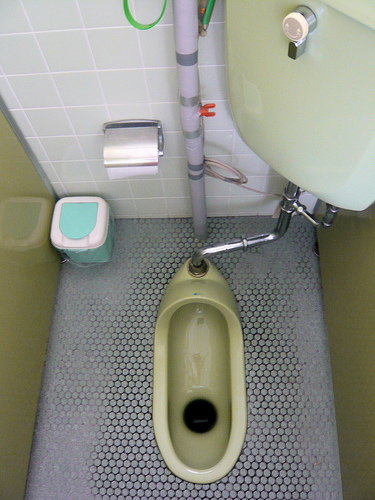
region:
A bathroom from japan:
[3, 2, 368, 493]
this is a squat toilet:
[149, 78, 370, 487]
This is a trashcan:
[47, 197, 120, 259]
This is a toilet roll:
[86, 117, 170, 177]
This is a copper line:
[187, 147, 301, 220]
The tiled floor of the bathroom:
[39, 208, 340, 491]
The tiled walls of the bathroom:
[0, 2, 320, 218]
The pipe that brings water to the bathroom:
[143, 0, 231, 242]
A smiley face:
[274, 8, 317, 51]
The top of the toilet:
[222, 2, 374, 216]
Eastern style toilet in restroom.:
[148, 252, 253, 487]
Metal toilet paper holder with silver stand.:
[99, 115, 164, 181]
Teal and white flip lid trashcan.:
[51, 190, 120, 268]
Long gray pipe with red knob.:
[169, 2, 219, 243]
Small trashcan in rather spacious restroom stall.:
[44, 192, 117, 263]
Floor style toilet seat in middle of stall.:
[147, 240, 250, 487]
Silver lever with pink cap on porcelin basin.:
[272, 1, 324, 62]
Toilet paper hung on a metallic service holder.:
[92, 115, 168, 183]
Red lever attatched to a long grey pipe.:
[167, 10, 220, 237]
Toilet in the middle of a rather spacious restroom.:
[149, 239, 252, 485]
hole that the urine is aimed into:
[181, 395, 218, 435]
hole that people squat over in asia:
[164, 295, 233, 472]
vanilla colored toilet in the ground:
[149, 253, 250, 487]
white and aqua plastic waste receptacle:
[46, 192, 117, 270]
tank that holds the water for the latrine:
[222, 0, 374, 214]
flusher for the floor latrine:
[279, 4, 318, 62]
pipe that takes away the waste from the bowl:
[171, 0, 208, 240]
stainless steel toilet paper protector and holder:
[98, 117, 166, 169]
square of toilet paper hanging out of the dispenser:
[105, 163, 160, 182]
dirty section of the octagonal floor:
[80, 215, 323, 498]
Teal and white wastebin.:
[52, 196, 115, 264]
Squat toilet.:
[153, 255, 246, 482]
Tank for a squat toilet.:
[188, 0, 373, 278]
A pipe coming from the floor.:
[171, 0, 208, 242]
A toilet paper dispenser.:
[101, 119, 163, 180]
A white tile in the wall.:
[31, 28, 97, 74]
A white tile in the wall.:
[47, 159, 95, 183]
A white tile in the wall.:
[132, 195, 168, 214]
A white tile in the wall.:
[231, 175, 264, 195]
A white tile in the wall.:
[0, 0, 34, 35]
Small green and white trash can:
[43, 196, 119, 269]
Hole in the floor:
[177, 392, 220, 437]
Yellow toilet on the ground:
[140, 250, 257, 488]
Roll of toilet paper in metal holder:
[97, 123, 164, 183]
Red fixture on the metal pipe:
[196, 101, 215, 120]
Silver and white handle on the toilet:
[274, 5, 320, 64]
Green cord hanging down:
[120, 0, 166, 30]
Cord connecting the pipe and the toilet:
[196, 154, 289, 221]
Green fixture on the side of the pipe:
[195, 1, 218, 36]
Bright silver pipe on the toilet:
[180, 166, 338, 281]